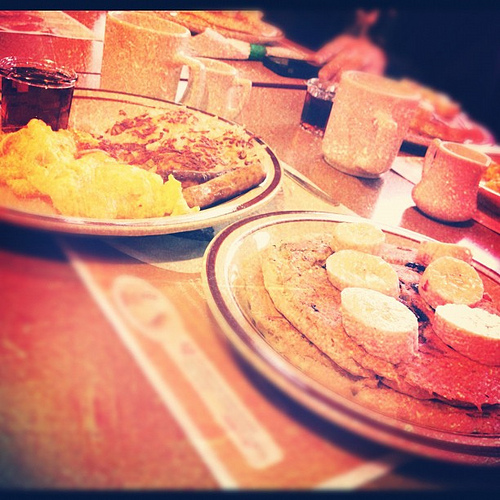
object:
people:
[313, 4, 443, 89]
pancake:
[223, 208, 499, 433]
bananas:
[330, 214, 499, 362]